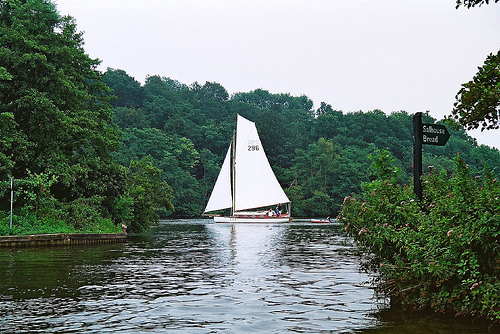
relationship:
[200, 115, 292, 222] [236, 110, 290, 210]
boat has sail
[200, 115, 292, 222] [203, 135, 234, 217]
boat has sail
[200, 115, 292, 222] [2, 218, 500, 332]
boat in water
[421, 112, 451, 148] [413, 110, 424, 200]
sign in on a pole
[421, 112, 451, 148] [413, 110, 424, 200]
sign on a pole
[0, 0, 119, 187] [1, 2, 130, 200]
leaves has leaves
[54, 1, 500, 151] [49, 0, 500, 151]
clouds in clouds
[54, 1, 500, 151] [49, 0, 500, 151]
clouds are in clouds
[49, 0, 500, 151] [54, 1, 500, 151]
clouds has clouds